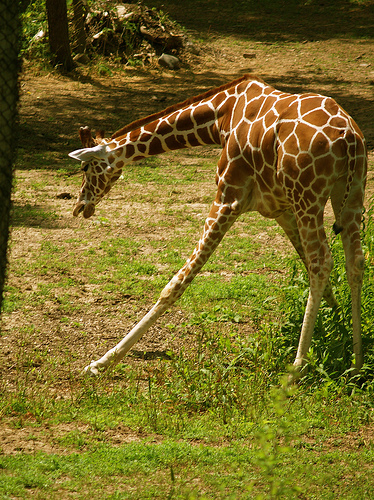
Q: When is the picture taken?
A: Daytime.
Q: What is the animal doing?
A: Bending over.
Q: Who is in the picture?
A: A giraffe.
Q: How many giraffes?
A: One.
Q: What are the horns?
A: Ossicones.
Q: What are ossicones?
A: Horn like growths.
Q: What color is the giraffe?
A: Tan and white.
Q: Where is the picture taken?
A: Near giraffe.